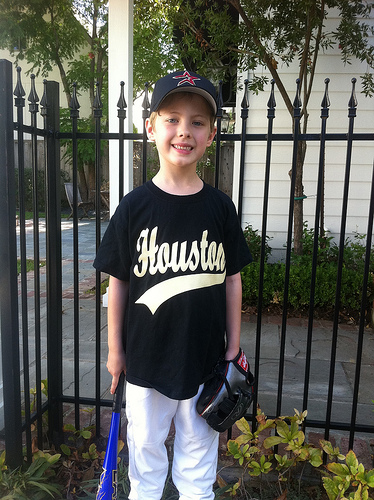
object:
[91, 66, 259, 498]
boy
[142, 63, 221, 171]
head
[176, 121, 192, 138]
nose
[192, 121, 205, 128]
eye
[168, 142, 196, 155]
mouth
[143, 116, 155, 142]
ear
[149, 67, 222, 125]
cap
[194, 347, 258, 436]
baseball glove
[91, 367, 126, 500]
baseball bat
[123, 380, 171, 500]
leg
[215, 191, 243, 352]
arm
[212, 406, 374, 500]
plant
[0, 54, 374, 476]
fence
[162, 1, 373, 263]
tree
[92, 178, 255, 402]
shirt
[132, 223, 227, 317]
name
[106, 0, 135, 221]
pillar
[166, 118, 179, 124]
eye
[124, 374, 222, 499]
pants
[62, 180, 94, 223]
chair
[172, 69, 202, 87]
star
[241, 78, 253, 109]
point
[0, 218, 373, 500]
ground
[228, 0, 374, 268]
house